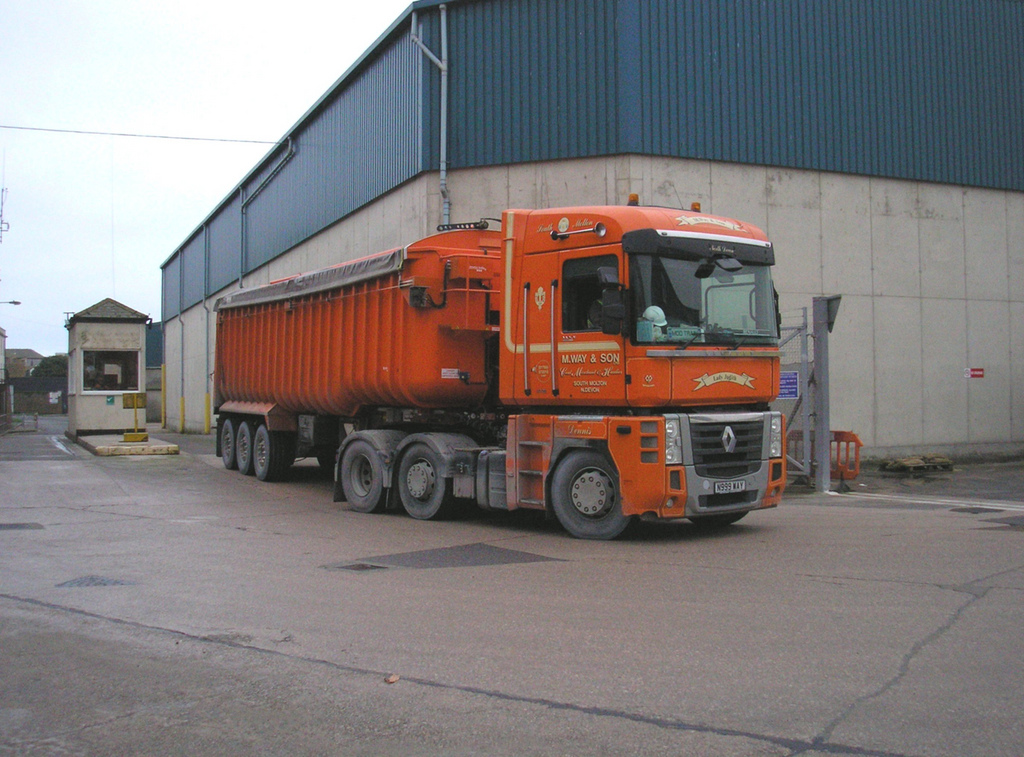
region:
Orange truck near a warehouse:
[211, 207, 788, 537]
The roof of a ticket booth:
[65, 297, 151, 324]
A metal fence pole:
[811, 294, 838, 497]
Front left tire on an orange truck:
[548, 444, 631, 540]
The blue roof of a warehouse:
[162, 3, 1022, 329]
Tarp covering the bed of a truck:
[213, 243, 410, 316]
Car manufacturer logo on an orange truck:
[722, 424, 738, 456]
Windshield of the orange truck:
[630, 248, 782, 348]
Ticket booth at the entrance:
[67, 297, 150, 435]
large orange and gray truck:
[155, 214, 814, 562]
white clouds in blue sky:
[57, 33, 131, 85]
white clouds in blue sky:
[173, 103, 228, 143]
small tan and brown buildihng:
[66, 280, 162, 445]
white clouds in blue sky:
[63, 217, 140, 279]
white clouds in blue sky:
[227, 8, 284, 43]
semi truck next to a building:
[205, 196, 781, 551]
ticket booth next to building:
[63, 293, 155, 448]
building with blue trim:
[151, 0, 1022, 468]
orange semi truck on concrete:
[209, 197, 791, 546]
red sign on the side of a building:
[958, 355, 993, 385]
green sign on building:
[100, 388, 120, 409]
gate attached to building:
[780, 290, 847, 502]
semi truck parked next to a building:
[205, 189, 788, 550]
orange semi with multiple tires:
[208, 195, 793, 551]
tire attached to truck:
[341, 446, 381, 501]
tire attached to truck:
[395, 450, 449, 514]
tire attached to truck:
[556, 453, 626, 527]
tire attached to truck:
[252, 425, 284, 480]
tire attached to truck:
[227, 424, 257, 472]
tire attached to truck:
[212, 414, 239, 471]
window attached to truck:
[644, 248, 778, 347]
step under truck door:
[518, 436, 542, 501]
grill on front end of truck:
[683, 420, 773, 512]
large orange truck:
[225, 168, 856, 565]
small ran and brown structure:
[61, 288, 160, 448]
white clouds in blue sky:
[193, 37, 266, 89]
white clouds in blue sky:
[49, 51, 133, 109]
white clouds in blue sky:
[52, 22, 154, 121]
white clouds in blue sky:
[38, 162, 102, 232]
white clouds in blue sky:
[84, 60, 145, 138]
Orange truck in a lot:
[168, 221, 829, 545]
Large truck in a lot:
[186, 253, 820, 542]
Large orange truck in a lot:
[201, 243, 803, 535]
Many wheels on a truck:
[211, 401, 652, 531]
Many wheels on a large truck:
[209, 398, 631, 523]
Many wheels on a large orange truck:
[214, 394, 635, 538]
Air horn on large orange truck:
[544, 214, 615, 241]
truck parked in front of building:
[188, 191, 809, 547]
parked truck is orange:
[207, 194, 795, 556]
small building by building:
[58, 284, 157, 437]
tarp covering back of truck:
[205, 246, 422, 317]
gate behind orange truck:
[759, 280, 857, 516]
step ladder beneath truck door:
[500, 422, 557, 515]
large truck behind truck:
[137, 2, 1022, 505]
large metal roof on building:
[147, 2, 1021, 331]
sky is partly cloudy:
[6, 2, 403, 370]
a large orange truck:
[197, 195, 793, 549]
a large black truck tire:
[545, 449, 631, 538]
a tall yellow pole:
[150, 360, 176, 424]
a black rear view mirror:
[590, 277, 629, 338]